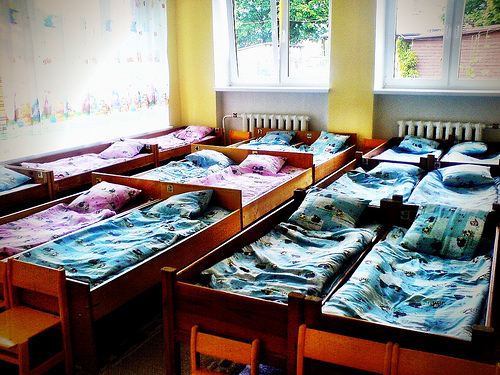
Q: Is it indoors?
A: Yes, it is indoors.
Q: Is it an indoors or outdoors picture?
A: It is indoors.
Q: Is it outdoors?
A: No, it is indoors.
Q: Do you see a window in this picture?
A: Yes, there is a window.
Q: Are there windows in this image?
A: Yes, there is a window.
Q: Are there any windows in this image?
A: Yes, there is a window.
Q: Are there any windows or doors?
A: Yes, there is a window.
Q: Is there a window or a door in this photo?
A: Yes, there is a window.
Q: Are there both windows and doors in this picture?
A: No, there is a window but no doors.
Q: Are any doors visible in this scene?
A: No, there are no doors.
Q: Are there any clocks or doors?
A: No, there are no doors or clocks.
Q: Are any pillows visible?
A: Yes, there is a pillow.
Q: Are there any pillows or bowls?
A: Yes, there is a pillow.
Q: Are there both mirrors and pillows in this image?
A: No, there is a pillow but no mirrors.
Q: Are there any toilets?
A: No, there are no toilets.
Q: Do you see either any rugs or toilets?
A: No, there are no toilets or rugs.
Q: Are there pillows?
A: Yes, there is a pillow.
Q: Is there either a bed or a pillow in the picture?
A: Yes, there is a pillow.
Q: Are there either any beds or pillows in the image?
A: Yes, there is a pillow.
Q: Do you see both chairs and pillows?
A: Yes, there are both a pillow and a chair.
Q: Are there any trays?
A: No, there are no trays.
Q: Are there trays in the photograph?
A: No, there are no trays.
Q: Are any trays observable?
A: No, there are no trays.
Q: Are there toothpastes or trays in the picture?
A: No, there are no trays or toothpastes.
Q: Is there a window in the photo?
A: Yes, there is a window.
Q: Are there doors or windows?
A: Yes, there is a window.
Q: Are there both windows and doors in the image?
A: No, there is a window but no doors.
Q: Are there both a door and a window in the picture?
A: No, there is a window but no doors.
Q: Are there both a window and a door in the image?
A: No, there is a window but no doors.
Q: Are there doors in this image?
A: No, there are no doors.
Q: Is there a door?
A: No, there are no doors.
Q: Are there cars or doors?
A: No, there are no doors or cars.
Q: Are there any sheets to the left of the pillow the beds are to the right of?
A: Yes, there is a sheet to the left of the pillow.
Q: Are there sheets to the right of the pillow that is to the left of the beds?
A: No, the sheet is to the left of the pillow.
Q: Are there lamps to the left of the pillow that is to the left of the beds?
A: No, there is a sheet to the left of the pillow.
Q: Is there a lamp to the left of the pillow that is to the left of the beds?
A: No, there is a sheet to the left of the pillow.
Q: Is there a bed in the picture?
A: Yes, there is a bed.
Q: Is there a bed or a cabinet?
A: Yes, there is a bed.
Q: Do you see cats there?
A: No, there are no cats.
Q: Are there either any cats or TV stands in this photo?
A: No, there are no cats or TV stands.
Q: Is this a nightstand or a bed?
A: This is a bed.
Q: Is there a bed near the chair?
A: Yes, there is a bed near the chair.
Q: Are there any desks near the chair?
A: No, there is a bed near the chair.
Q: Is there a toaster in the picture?
A: No, there are no toasters.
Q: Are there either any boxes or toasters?
A: No, there are no toasters or boxes.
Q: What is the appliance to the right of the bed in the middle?
A: The appliance is a radiator.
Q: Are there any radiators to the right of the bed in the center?
A: Yes, there is a radiator to the right of the bed.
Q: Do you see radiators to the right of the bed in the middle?
A: Yes, there is a radiator to the right of the bed.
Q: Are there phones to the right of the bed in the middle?
A: No, there is a radiator to the right of the bed.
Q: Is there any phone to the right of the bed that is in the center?
A: No, there is a radiator to the right of the bed.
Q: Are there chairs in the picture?
A: Yes, there is a chair.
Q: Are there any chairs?
A: Yes, there is a chair.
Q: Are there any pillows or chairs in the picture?
A: Yes, there is a chair.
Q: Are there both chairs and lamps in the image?
A: No, there is a chair but no lamps.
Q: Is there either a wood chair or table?
A: Yes, there is a wood chair.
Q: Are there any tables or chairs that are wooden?
A: Yes, the chair is wooden.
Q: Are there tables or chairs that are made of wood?
A: Yes, the chair is made of wood.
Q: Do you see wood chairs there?
A: Yes, there is a wood chair.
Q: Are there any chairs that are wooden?
A: Yes, there is a chair that is wooden.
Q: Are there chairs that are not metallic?
A: Yes, there is a wooden chair.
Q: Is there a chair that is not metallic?
A: Yes, there is a wooden chair.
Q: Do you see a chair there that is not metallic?
A: Yes, there is a wooden chair.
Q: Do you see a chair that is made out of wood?
A: Yes, there is a chair that is made of wood.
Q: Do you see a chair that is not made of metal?
A: Yes, there is a chair that is made of wood.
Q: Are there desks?
A: No, there are no desks.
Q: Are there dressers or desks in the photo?
A: No, there are no desks or dressers.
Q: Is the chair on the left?
A: Yes, the chair is on the left of the image.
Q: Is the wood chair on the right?
A: No, the chair is on the left of the image.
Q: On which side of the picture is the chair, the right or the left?
A: The chair is on the left of the image.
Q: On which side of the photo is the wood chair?
A: The chair is on the left of the image.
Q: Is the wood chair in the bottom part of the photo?
A: Yes, the chair is in the bottom of the image.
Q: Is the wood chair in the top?
A: No, the chair is in the bottom of the image.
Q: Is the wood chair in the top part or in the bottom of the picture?
A: The chair is in the bottom of the image.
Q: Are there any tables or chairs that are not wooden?
A: No, there is a chair but it is wooden.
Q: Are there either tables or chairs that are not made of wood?
A: No, there is a chair but it is made of wood.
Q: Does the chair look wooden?
A: Yes, the chair is wooden.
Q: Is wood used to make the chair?
A: Yes, the chair is made of wood.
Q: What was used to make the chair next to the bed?
A: The chair is made of wood.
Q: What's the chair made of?
A: The chair is made of wood.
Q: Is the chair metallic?
A: No, the chair is wooden.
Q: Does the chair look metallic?
A: No, the chair is wooden.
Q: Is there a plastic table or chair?
A: No, there is a chair but it is wooden.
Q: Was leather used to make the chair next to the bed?
A: No, the chair is made of wood.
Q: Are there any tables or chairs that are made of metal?
A: No, there is a chair but it is made of wood.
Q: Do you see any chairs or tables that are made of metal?
A: No, there is a chair but it is made of wood.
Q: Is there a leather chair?
A: No, there is a chair but it is made of wood.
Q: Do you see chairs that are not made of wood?
A: No, there is a chair but it is made of wood.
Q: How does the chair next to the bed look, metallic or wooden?
A: The chair is wooden.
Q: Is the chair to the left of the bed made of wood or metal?
A: The chair is made of wood.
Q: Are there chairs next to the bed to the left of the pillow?
A: Yes, there is a chair next to the bed.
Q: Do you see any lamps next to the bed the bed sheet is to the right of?
A: No, there is a chair next to the bed.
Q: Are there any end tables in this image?
A: No, there are no end tables.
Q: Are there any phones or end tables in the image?
A: No, there are no end tables or phones.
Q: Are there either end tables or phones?
A: No, there are no end tables or phones.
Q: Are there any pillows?
A: Yes, there is a pillow.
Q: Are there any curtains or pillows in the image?
A: Yes, there is a pillow.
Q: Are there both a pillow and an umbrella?
A: No, there is a pillow but no umbrellas.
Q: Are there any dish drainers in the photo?
A: No, there are no dish drainers.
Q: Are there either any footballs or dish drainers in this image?
A: No, there are no dish drainers or footballs.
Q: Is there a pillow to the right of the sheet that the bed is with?
A: Yes, there is a pillow to the right of the sheet.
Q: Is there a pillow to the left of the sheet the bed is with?
A: No, the pillow is to the right of the bed sheet.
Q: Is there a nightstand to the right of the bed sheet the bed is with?
A: No, there is a pillow to the right of the sheet.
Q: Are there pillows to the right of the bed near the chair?
A: Yes, there is a pillow to the right of the bed.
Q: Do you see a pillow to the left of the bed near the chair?
A: No, the pillow is to the right of the bed.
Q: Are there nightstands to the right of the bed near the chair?
A: No, there is a pillow to the right of the bed.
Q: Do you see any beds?
A: Yes, there is a bed.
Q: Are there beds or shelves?
A: Yes, there is a bed.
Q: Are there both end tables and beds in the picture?
A: No, there is a bed but no end tables.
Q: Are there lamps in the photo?
A: No, there are no lamps.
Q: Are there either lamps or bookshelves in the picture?
A: No, there are no lamps or bookshelves.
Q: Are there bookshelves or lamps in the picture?
A: No, there are no lamps or bookshelves.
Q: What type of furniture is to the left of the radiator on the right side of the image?
A: The piece of furniture is a bed.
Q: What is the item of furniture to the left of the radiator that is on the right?
A: The piece of furniture is a bed.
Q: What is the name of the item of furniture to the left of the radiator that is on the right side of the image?
A: The piece of furniture is a bed.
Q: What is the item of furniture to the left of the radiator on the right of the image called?
A: The piece of furniture is a bed.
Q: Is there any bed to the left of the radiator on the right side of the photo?
A: Yes, there is a bed to the left of the radiator.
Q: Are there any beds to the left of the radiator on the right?
A: Yes, there is a bed to the left of the radiator.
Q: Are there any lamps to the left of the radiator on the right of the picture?
A: No, there is a bed to the left of the radiator.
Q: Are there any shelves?
A: No, there are no shelves.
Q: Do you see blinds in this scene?
A: No, there are no blinds.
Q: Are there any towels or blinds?
A: No, there are no blinds or towels.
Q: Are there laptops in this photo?
A: No, there are no laptops.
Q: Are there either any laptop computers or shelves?
A: No, there are no laptop computers or shelves.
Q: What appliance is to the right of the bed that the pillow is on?
A: The appliance is a radiator.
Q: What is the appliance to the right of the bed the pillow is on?
A: The appliance is a radiator.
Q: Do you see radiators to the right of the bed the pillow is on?
A: Yes, there is a radiator to the right of the bed.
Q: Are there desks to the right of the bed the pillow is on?
A: No, there is a radiator to the right of the bed.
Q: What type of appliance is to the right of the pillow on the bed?
A: The appliance is a radiator.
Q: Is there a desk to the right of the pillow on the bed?
A: No, there is a radiator to the right of the pillow.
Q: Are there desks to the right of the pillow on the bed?
A: No, there is a radiator to the right of the pillow.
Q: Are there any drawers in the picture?
A: No, there are no drawers.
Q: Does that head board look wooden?
A: Yes, the head board is wooden.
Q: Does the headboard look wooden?
A: Yes, the headboard is wooden.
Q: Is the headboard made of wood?
A: Yes, the headboard is made of wood.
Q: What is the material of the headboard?
A: The headboard is made of wood.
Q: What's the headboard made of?
A: The headboard is made of wood.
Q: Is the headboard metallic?
A: No, the headboard is wooden.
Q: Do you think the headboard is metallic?
A: No, the headboard is wooden.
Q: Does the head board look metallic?
A: No, the head board is wooden.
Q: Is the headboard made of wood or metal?
A: The headboard is made of wood.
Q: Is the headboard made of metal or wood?
A: The headboard is made of wood.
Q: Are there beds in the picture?
A: Yes, there is a bed.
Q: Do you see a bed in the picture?
A: Yes, there is a bed.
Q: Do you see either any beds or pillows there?
A: Yes, there is a bed.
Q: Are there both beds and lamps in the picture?
A: No, there is a bed but no lamps.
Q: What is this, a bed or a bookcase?
A: This is a bed.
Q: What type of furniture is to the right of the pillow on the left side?
A: The piece of furniture is a bed.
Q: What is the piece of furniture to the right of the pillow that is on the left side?
A: The piece of furniture is a bed.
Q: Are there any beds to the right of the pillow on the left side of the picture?
A: Yes, there is a bed to the right of the pillow.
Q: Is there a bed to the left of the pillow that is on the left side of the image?
A: No, the bed is to the right of the pillow.